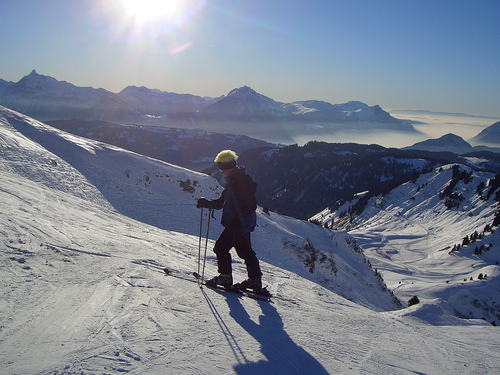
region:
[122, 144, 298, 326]
A person with snowboard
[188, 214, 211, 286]
A person holding the skipoles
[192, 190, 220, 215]
A person wearing black color gloves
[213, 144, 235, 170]
A person wearing helmet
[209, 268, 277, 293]
A person wearing pair of shoes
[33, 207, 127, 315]
White color snow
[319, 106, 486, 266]
A big mountain covered with snow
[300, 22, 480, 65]
A blue color sky with clouds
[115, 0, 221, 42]
Sun lights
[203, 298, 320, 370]
Shadow of the person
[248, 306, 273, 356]
part of a shade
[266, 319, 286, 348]
part of a shade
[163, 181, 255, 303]
par tof a hokker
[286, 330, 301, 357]
part of a shade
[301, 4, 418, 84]
this is the sky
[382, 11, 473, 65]
the sky is blue in color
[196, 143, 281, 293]
this is a man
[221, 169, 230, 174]
the man is light skinned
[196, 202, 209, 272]
this is a stick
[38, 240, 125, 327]
this is the snow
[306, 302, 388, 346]
the snow is white in color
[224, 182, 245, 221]
this is the jacket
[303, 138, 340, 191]
this is a tree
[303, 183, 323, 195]
the leaves are green in color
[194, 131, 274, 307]
a man on a snowy slope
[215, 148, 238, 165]
a green and black knit cap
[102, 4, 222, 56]
a bright sun shining above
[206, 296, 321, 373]
a shadow on the snow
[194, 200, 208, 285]
hands gripping ski poles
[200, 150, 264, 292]
a man wearing a blue jacket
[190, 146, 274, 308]
a man wearing black pants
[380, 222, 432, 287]
ski tracks in the snow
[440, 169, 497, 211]
black rocks jutting out through the snow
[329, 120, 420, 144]
thick white mountain mist